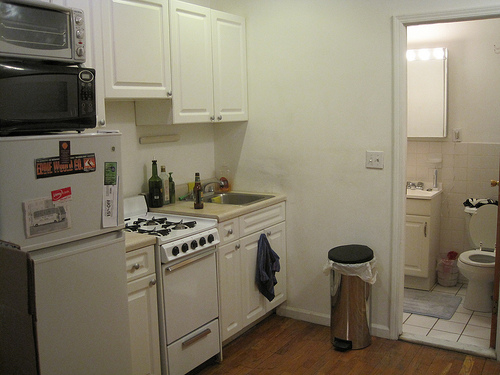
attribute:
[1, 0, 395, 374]
kitchen — white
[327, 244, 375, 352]
trashcan — shiny, grey, chrome, silver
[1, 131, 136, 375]
fridge — white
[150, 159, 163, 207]
bottle — open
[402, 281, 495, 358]
floor — white, tiled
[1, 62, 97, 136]
microwave — black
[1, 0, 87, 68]
microwave — white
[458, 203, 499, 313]
toilet — white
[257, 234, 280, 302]
towel — hanging, dark, black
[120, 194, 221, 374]
stove — gas, white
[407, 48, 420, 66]
light — on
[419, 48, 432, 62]
light — on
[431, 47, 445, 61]
light — on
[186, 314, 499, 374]
floor — wooden, hardwood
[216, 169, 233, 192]
bottle — plastic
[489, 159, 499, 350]
door — open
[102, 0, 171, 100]
cupboards — white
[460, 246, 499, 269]
toilet-seat — white